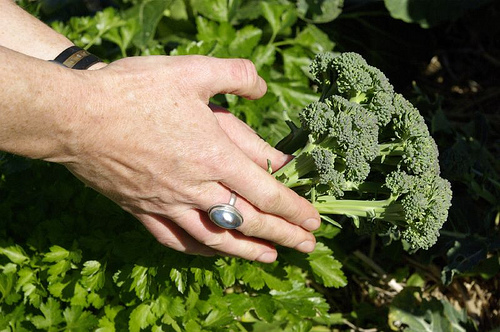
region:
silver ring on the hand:
[194, 176, 261, 241]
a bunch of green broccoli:
[251, 22, 473, 264]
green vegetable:
[256, 31, 473, 256]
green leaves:
[4, 216, 404, 329]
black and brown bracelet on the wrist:
[29, 26, 103, 86]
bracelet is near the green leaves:
[20, 33, 133, 93]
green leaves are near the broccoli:
[56, 4, 451, 326]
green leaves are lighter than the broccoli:
[64, 1, 447, 238]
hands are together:
[40, 11, 332, 277]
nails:
[290, 209, 324, 253]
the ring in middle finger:
[172, 155, 297, 324]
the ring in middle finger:
[118, 125, 333, 299]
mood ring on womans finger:
[208, 190, 247, 236]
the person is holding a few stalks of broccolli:
[76, 52, 466, 262]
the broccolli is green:
[308, 50, 458, 252]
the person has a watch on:
[45, 38, 107, 70]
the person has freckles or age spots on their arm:
[0, 48, 329, 277]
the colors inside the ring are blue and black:
[211, 206, 246, 231]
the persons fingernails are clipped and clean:
[301, 216, 321, 232]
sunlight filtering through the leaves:
[439, 281, 487, 317]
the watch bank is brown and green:
[51, 43, 107, 69]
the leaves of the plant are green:
[47, 247, 77, 265]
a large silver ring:
[128, 130, 273, 252]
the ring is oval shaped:
[163, 173, 357, 288]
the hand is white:
[62, 49, 388, 325]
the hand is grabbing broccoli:
[64, 22, 473, 279]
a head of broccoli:
[204, 11, 476, 221]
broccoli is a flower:
[130, 30, 487, 300]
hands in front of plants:
[99, 17, 439, 278]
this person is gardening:
[94, 16, 476, 311]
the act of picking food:
[101, 6, 496, 287]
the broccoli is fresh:
[99, 25, 492, 285]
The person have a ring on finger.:
[202, 183, 247, 240]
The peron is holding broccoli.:
[245, 61, 452, 242]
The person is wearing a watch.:
[30, 26, 102, 71]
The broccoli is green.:
[287, 35, 442, 260]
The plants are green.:
[21, 238, 307, 329]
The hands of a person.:
[107, 63, 337, 268]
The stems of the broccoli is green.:
[271, 118, 363, 237]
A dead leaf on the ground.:
[416, 257, 499, 318]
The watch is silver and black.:
[46, 34, 111, 86]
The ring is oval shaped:
[194, 179, 254, 241]